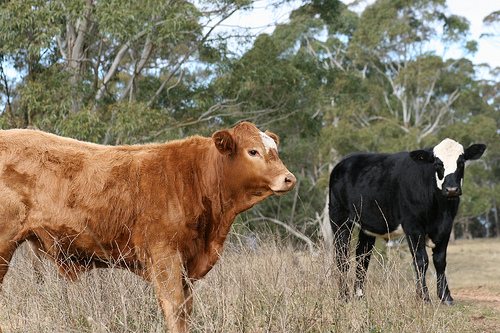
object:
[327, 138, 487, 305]
cow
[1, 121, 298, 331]
cow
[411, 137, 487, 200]
head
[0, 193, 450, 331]
grass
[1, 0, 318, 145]
tree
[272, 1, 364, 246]
tree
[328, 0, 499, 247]
tree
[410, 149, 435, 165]
ear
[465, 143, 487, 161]
ear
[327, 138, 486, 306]
coat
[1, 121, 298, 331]
coat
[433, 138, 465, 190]
patch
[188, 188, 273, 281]
bit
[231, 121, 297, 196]
face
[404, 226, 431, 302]
leg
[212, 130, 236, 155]
ear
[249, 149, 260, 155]
eye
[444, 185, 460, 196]
nose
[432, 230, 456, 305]
leg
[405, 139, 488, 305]
front